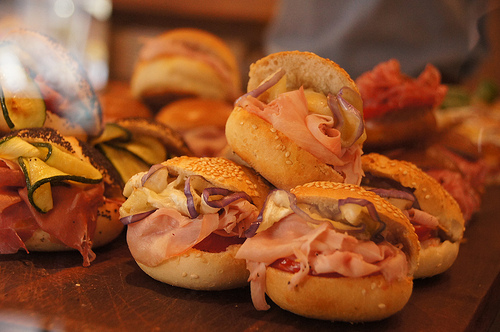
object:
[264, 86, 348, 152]
meat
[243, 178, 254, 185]
seeds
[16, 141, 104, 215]
vegetable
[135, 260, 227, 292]
buns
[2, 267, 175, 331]
table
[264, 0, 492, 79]
person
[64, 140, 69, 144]
seeds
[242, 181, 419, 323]
sandwiches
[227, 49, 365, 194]
sandwich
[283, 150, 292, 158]
sesame seeds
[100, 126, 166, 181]
zucchini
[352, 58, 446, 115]
tomatoes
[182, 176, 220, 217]
onions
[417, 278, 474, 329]
table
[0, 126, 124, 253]
sandwich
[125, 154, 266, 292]
sandwich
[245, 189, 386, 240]
onion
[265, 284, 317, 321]
bun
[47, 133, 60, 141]
poppy seeds